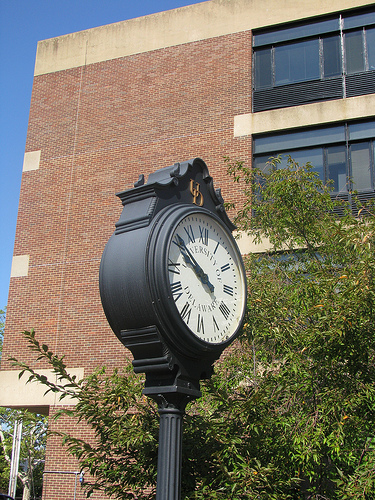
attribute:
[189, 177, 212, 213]
letters — gold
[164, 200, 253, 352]
clock — metal, black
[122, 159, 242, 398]
frame — black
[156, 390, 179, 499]
pole — steel, metal, black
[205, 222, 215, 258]
numerals — black, roman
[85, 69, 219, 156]
building — brick, tan, red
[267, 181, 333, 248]
leaves — green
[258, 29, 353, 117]
windows — hidden, big, black, dark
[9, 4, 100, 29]
sky — blue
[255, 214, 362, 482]
trees — leafy, green, wood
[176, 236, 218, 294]
hands — black